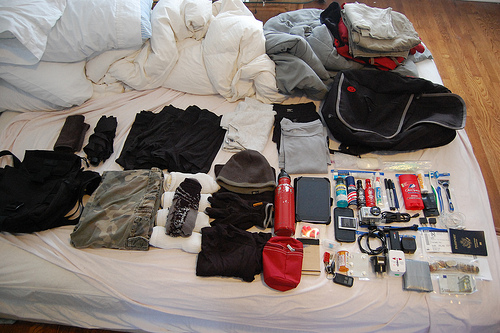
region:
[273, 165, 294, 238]
a red bottle on a bed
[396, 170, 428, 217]
a red deodorant container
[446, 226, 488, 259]
a blue passport on a bed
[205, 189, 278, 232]
a pair of black gloves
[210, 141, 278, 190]
a gray knit hat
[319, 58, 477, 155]
a black bag on a bed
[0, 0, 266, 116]
a wad of bedding on a bed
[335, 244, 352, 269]
a pill bottle on a bed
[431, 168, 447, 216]
a blue and white toothbrush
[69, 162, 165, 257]
folded camouflage pants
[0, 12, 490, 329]
Mattress on on hardwood floor.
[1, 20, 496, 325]
Passport on mattress with white sheet.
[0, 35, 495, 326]
Skull cap on mattress with white sheet.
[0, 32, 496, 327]
Army pants on mattress with white sheet.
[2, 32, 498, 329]
Black back pack on bed with white sheet.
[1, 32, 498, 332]
Adapter on mattress with white sheet.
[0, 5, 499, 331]
White pillows on mattress with white sheets.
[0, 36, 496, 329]
Ink pens on mattress with white sheets.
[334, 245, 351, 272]
White label on pill bottle.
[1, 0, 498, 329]
T-shirts on mattress with white sheet.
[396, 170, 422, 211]
red deodorant container on bed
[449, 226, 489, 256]
passport laying on bed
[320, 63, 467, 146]
empty black backpack on bed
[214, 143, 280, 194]
two tone grey skull cap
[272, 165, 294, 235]
red metal water bottle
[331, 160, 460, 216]
toiletries lined up on bed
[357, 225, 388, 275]
rolled up charger cord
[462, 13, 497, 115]
wooden plank floor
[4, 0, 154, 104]
pillows stacked on edge of bed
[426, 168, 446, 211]
two blue and white toothbrushes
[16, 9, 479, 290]
this is a bunch of items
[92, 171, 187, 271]
these are shorts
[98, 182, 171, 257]
this is a camo pattern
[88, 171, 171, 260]
these are green and brown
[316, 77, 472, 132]
this is a backpack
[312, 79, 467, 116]
the back pack is black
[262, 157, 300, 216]
this is a metal waterbottle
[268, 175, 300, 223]
the water bottle is red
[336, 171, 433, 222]
these are bathroom items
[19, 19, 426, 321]
this is stuff for packing for a vacation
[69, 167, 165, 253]
Folded camouflage cargo shorts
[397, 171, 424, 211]
Old Spice deodorant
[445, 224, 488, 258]
Black passport lying on a bed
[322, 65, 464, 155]
Black backpack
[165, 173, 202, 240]
Rolled up gray and black socks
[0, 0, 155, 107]
Pile of four pillows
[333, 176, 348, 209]
Small plastic bottle of mouthwash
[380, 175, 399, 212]
Two black Sharpie markers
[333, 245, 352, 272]
Small plastic orange bottle of pills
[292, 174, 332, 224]
Ipad in a black case